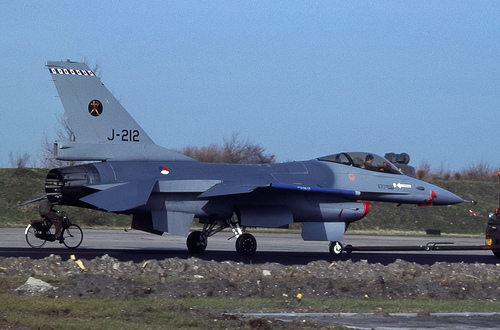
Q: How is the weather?
A: It is clear.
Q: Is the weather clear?
A: Yes, it is clear.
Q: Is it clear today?
A: Yes, it is clear.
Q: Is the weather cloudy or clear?
A: It is clear.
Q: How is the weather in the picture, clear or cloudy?
A: It is clear.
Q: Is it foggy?
A: No, it is clear.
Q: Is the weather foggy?
A: No, it is clear.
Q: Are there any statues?
A: No, there are no statues.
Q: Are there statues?
A: No, there are no statues.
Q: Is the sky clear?
A: Yes, the sky is clear.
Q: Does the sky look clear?
A: Yes, the sky is clear.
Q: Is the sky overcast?
A: No, the sky is clear.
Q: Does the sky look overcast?
A: No, the sky is clear.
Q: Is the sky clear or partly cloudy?
A: The sky is clear.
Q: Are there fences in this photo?
A: No, there are no fences.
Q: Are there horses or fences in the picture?
A: No, there are no fences or horses.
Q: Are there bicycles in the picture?
A: Yes, there is a bicycle.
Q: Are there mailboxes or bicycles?
A: Yes, there is a bicycle.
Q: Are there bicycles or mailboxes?
A: Yes, there is a bicycle.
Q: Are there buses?
A: No, there are no buses.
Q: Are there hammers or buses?
A: No, there are no buses or hammers.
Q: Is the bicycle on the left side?
A: Yes, the bicycle is on the left of the image.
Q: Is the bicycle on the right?
A: No, the bicycle is on the left of the image.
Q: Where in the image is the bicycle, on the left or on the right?
A: The bicycle is on the left of the image.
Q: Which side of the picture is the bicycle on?
A: The bicycle is on the left of the image.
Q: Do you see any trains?
A: No, there are no trains.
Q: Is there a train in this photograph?
A: No, there are no trains.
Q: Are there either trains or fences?
A: No, there are no trains or fences.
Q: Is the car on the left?
A: No, the car is on the right of the image.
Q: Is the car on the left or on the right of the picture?
A: The car is on the right of the image.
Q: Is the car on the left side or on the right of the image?
A: The car is on the right of the image.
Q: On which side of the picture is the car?
A: The car is on the right of the image.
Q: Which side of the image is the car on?
A: The car is on the right of the image.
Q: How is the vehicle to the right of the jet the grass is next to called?
A: The vehicle is a car.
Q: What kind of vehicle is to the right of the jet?
A: The vehicle is a car.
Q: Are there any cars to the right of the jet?
A: Yes, there is a car to the right of the jet.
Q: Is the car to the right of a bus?
A: No, the car is to the right of a jet.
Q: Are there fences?
A: No, there are no fences.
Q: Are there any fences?
A: No, there are no fences.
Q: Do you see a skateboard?
A: No, there are no skateboards.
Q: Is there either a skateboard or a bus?
A: No, there are no skateboards or buses.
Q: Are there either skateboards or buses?
A: No, there are no skateboards or buses.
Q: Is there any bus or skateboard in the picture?
A: No, there are no skateboards or buses.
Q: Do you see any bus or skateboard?
A: No, there are no skateboards or buses.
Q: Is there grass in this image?
A: Yes, there is grass.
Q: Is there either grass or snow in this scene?
A: Yes, there is grass.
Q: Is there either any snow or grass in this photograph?
A: Yes, there is grass.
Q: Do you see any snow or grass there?
A: Yes, there is grass.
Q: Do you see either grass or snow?
A: Yes, there is grass.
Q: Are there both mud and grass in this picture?
A: No, there is grass but no mud.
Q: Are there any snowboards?
A: No, there are no snowboards.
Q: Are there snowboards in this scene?
A: No, there are no snowboards.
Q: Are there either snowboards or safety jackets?
A: No, there are no snowboards or safety jackets.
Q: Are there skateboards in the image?
A: No, there are no skateboards.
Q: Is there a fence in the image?
A: No, there are no fences.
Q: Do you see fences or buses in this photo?
A: No, there are no fences or buses.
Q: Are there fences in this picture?
A: No, there are no fences.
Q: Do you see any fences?
A: No, there are no fences.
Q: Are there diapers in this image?
A: No, there are no diapers.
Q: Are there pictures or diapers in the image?
A: No, there are no diapers or pictures.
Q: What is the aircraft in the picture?
A: The aircraft is a jet.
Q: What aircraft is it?
A: The aircraft is a jet.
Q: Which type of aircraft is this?
A: This is a jet.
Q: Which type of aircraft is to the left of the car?
A: The aircraft is a jet.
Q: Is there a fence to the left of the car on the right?
A: No, there is a jet to the left of the car.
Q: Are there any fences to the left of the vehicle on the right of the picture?
A: No, there is a jet to the left of the car.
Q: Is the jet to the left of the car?
A: Yes, the jet is to the left of the car.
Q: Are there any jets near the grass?
A: Yes, there is a jet near the grass.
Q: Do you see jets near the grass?
A: Yes, there is a jet near the grass.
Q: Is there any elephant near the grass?
A: No, there is a jet near the grass.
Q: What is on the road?
A: The jet is on the road.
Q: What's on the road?
A: The jet is on the road.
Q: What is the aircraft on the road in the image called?
A: The aircraft is a jet.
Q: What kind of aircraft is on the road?
A: The aircraft is a jet.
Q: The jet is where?
A: The jet is on the road.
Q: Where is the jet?
A: The jet is on the road.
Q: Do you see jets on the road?
A: Yes, there is a jet on the road.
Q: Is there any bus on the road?
A: No, there is a jet on the road.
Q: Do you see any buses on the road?
A: No, there is a jet on the road.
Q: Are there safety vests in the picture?
A: No, there are no safety vests.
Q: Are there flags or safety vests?
A: No, there are no safety vests or flags.